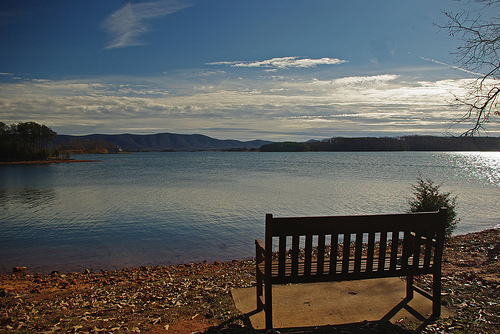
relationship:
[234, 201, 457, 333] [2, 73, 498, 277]
bench has view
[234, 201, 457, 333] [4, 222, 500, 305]
bench near shore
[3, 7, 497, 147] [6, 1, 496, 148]
clouds in sky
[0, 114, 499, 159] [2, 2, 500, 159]
mountains are in background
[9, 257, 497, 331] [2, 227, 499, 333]
leaves are on ground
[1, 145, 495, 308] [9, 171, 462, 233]
water has reflection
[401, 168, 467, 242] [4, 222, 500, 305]
tree on shore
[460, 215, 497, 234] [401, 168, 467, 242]
reflection of tree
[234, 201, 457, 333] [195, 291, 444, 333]
bench has shadow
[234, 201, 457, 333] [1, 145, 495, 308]
bench facing water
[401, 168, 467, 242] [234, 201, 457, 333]
tree next to bench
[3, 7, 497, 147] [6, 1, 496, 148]
clouds are in sky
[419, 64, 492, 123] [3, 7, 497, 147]
sun behind clouds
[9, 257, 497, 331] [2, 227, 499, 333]
leaves on ground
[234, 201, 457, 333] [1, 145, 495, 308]
bench overlooks water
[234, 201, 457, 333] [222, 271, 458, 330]
bench on cement pad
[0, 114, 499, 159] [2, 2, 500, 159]
mountains in background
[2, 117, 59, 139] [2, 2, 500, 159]
trees in background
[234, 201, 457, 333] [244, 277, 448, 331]
bench has legs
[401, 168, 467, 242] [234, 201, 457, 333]
tree beside bench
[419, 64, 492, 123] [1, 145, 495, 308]
sun reflected in water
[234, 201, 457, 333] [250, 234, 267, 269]
bench has armrest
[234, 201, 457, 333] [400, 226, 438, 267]
bench has armrest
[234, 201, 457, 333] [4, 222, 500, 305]
bench on shore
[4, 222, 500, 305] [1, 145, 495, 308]
shore along water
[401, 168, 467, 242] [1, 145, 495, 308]
tree by water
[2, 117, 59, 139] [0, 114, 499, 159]
trees in front of mountains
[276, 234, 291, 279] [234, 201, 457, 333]
slat on bench